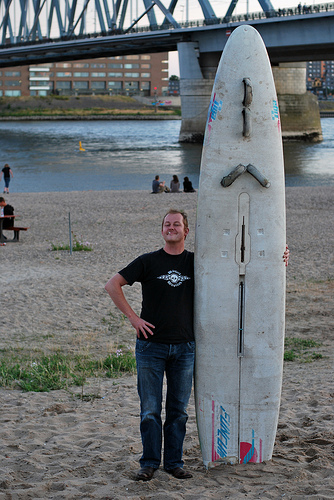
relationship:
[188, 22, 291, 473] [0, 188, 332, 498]
board in sand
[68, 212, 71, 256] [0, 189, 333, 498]
pipe sticking out of ground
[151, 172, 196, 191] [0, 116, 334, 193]
people sitting next to river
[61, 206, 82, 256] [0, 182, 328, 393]
pipe sticking out of sand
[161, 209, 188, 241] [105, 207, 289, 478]
head of person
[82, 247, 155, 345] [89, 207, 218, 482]
arm of person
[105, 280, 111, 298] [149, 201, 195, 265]
elbow of person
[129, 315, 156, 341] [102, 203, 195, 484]
hand of man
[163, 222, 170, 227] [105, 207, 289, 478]
eye of person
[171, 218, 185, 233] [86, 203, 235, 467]
eye of person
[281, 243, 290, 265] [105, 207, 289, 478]
fingers of person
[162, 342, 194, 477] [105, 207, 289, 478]
leg of person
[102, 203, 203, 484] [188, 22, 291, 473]
man holding board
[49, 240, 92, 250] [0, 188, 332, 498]
grass patch in sand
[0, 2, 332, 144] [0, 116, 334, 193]
bridge over river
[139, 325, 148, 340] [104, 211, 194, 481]
finger of person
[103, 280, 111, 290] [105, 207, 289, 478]
elbow of person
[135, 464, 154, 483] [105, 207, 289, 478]
feet of person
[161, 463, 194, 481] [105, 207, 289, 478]
feet of person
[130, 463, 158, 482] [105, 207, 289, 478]
feet of person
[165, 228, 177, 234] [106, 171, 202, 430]
mouth of person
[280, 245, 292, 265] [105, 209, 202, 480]
finger of person